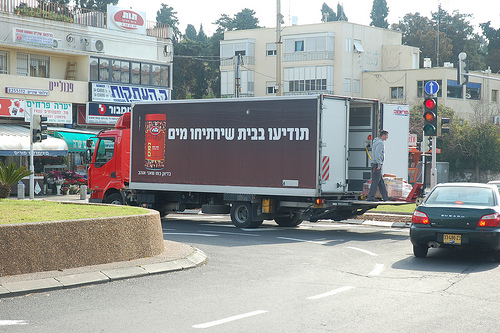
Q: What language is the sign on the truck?
A: Hebrew.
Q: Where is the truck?
A: The intersection.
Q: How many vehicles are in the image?
A: Two.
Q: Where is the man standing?
A: On the back of the truck.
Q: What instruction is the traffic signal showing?
A: Stop.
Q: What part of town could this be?
A: Downtown.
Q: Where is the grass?
A: On the median strip.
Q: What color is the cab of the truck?
A: Red.